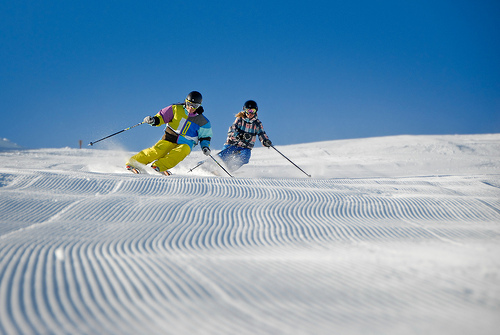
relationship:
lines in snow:
[190, 178, 299, 248] [21, 169, 494, 328]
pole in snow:
[199, 152, 235, 178] [21, 169, 494, 328]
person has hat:
[221, 100, 275, 185] [246, 99, 258, 109]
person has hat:
[133, 84, 213, 179] [188, 90, 204, 103]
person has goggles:
[221, 100, 275, 185] [245, 109, 257, 115]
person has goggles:
[133, 84, 213, 179] [185, 97, 203, 110]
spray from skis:
[100, 131, 127, 171] [126, 162, 181, 182]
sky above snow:
[21, 13, 486, 89] [21, 169, 494, 328]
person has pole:
[221, 100, 275, 185] [270, 141, 319, 181]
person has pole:
[133, 84, 213, 179] [199, 152, 235, 178]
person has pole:
[133, 84, 213, 179] [73, 114, 149, 153]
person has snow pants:
[133, 84, 213, 179] [125, 133, 190, 175]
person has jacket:
[133, 84, 213, 179] [149, 102, 212, 156]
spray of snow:
[100, 131, 127, 171] [21, 169, 494, 328]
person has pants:
[221, 100, 275, 185] [217, 144, 254, 171]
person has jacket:
[221, 100, 275, 185] [222, 111, 275, 150]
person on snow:
[221, 100, 275, 185] [21, 169, 494, 328]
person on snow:
[133, 84, 213, 179] [21, 169, 494, 328]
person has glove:
[221, 100, 275, 185] [257, 135, 274, 147]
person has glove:
[133, 84, 213, 179] [144, 117, 157, 127]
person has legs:
[133, 84, 213, 179] [145, 144, 190, 165]